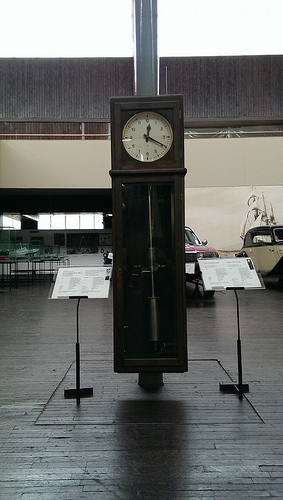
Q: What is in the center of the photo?
A: A grandfather clock.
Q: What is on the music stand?
A: Information.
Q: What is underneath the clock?
A: Square on floor.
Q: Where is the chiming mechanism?
A: On clock.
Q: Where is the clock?
A: Foreground.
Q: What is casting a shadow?
A: Clock.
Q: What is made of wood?
A: Clock frame.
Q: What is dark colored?
A: Wood.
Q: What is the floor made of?
A: Hard wood.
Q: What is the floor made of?
A: Wood.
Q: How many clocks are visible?
A: One.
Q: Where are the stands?
A: On either side of the clock.